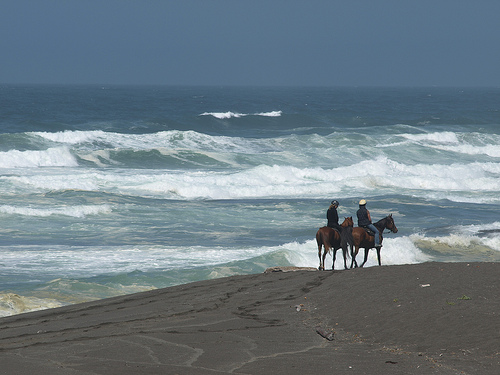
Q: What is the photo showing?
A: It is showing an ocean.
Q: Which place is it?
A: It is an ocean.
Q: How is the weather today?
A: It is stormy.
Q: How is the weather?
A: It is stormy.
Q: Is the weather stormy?
A: Yes, it is stormy.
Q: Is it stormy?
A: Yes, it is stormy.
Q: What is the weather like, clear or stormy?
A: It is stormy.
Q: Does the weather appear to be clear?
A: No, it is stormy.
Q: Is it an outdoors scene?
A: Yes, it is outdoors.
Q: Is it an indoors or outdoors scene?
A: It is outdoors.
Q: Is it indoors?
A: No, it is outdoors.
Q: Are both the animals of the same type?
A: Yes, all the animals are horses.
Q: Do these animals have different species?
A: No, all the animals are horses.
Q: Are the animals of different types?
A: No, all the animals are horses.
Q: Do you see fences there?
A: No, there are no fences.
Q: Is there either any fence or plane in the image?
A: No, there are no fences or airplanes.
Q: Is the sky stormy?
A: Yes, the sky is stormy.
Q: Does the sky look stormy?
A: Yes, the sky is stormy.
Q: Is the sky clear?
A: No, the sky is stormy.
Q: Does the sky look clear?
A: No, the sky is stormy.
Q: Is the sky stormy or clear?
A: The sky is stormy.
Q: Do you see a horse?
A: Yes, there is a horse.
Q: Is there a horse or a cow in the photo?
A: Yes, there is a horse.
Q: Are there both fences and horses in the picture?
A: No, there is a horse but no fences.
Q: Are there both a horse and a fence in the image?
A: No, there is a horse but no fences.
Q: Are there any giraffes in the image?
A: No, there are no giraffes.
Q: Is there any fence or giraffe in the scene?
A: No, there are no giraffes or fences.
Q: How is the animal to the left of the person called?
A: The animal is a horse.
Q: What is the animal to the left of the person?
A: The animal is a horse.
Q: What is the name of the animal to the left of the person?
A: The animal is a horse.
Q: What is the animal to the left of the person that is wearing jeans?
A: The animal is a horse.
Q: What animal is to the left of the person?
A: The animal is a horse.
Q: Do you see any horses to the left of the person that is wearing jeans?
A: Yes, there is a horse to the left of the person.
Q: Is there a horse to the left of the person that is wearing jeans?
A: Yes, there is a horse to the left of the person.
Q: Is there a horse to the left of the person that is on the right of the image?
A: Yes, there is a horse to the left of the person.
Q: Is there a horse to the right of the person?
A: No, the horse is to the left of the person.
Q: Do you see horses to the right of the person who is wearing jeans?
A: No, the horse is to the left of the person.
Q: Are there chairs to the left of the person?
A: No, there is a horse to the left of the person.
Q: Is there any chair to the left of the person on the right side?
A: No, there is a horse to the left of the person.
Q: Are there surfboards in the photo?
A: No, there are no surfboards.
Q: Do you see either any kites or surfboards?
A: No, there are no surfboards or kites.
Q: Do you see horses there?
A: Yes, there is a horse.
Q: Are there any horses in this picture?
A: Yes, there is a horse.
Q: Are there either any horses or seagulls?
A: Yes, there is a horse.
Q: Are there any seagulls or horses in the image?
A: Yes, there is a horse.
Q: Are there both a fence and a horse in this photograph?
A: No, there is a horse but no fences.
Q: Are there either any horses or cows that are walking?
A: Yes, the horse is walking.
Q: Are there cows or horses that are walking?
A: Yes, the horse is walking.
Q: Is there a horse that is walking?
A: Yes, there is a horse that is walking.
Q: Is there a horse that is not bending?
A: Yes, there is a horse that is walking.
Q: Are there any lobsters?
A: No, there are no lobsters.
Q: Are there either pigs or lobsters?
A: No, there are no lobsters or pigs.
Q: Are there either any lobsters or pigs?
A: No, there are no lobsters or pigs.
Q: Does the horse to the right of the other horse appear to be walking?
A: Yes, the horse is walking.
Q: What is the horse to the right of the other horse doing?
A: The horse is walking.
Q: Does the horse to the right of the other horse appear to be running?
A: No, the horse is walking.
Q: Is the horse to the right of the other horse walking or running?
A: The horse is walking.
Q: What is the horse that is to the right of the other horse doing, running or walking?
A: The horse is walking.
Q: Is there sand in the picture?
A: Yes, there is sand.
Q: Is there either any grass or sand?
A: Yes, there is sand.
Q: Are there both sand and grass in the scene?
A: No, there is sand but no grass.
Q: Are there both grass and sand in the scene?
A: No, there is sand but no grass.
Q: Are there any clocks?
A: No, there are no clocks.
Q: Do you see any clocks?
A: No, there are no clocks.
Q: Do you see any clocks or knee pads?
A: No, there are no clocks or knee pads.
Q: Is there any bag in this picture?
A: No, there are no bags.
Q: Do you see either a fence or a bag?
A: No, there are no bags or fences.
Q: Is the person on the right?
A: Yes, the person is on the right of the image.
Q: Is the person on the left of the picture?
A: No, the person is on the right of the image.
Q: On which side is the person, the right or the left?
A: The person is on the right of the image.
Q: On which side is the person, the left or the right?
A: The person is on the right of the image.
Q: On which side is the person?
A: The person is on the right of the image.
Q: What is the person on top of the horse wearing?
A: The person is wearing jeans.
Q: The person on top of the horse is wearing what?
A: The person is wearing jeans.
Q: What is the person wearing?
A: The person is wearing jeans.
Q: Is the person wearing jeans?
A: Yes, the person is wearing jeans.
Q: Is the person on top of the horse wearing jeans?
A: Yes, the person is wearing jeans.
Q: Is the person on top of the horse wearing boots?
A: No, the person is wearing jeans.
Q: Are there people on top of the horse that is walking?
A: Yes, there is a person on top of the horse.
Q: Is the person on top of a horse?
A: Yes, the person is on top of a horse.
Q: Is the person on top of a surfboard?
A: No, the person is on top of a horse.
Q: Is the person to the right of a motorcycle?
A: No, the person is to the right of the helmet.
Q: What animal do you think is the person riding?
A: The person is riding a horse.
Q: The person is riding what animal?
A: The person is riding a horse.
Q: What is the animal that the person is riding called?
A: The animal is a horse.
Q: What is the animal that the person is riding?
A: The animal is a horse.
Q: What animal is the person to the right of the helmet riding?
A: The person is riding a horse.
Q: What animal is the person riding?
A: The person is riding a horse.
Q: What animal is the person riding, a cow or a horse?
A: The person is riding a horse.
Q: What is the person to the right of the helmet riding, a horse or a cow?
A: The person is riding a horse.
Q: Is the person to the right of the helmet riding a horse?
A: Yes, the person is riding a horse.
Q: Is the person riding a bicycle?
A: No, the person is riding a horse.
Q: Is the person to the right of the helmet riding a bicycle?
A: No, the person is riding a horse.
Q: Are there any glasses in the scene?
A: No, there are no glasses.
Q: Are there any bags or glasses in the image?
A: No, there are no glasses or bags.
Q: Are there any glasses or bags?
A: No, there are no glasses or bags.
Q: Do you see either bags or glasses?
A: No, there are no glasses or bags.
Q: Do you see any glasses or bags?
A: No, there are no glasses or bags.